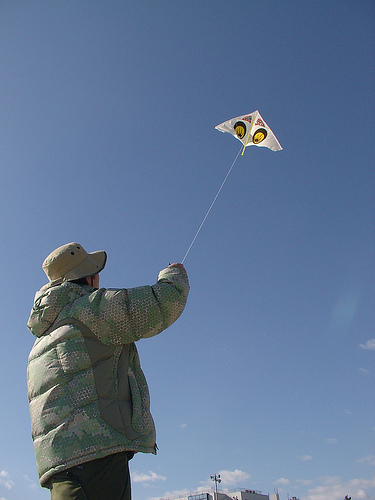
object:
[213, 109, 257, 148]
left side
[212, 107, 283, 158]
kite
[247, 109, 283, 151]
right side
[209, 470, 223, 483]
top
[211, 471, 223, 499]
speaker pole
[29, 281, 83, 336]
hood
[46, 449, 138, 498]
trousers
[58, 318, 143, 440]
part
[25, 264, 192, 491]
jacket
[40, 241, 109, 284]
top hat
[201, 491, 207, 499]
mirror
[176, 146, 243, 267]
string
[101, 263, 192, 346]
arm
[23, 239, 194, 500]
person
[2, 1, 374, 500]
air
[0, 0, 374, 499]
sky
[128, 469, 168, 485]
cloud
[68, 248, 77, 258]
hole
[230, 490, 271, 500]
top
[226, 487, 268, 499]
building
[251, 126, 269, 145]
design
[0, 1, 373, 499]
background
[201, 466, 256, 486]
cloud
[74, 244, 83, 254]
hole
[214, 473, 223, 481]
speaker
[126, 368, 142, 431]
pocket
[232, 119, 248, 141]
eye